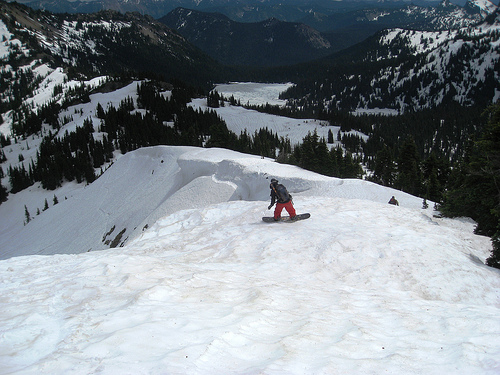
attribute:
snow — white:
[9, 146, 499, 373]